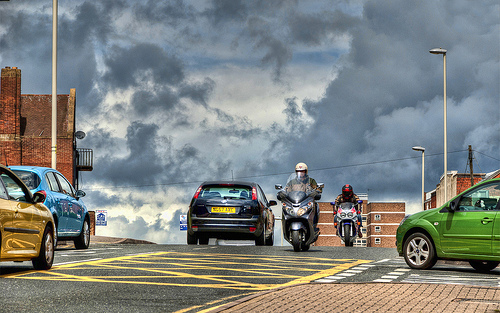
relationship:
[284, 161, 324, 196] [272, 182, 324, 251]
person riding bike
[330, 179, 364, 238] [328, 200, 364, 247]
person riding bike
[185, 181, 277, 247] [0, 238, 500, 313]
car on ground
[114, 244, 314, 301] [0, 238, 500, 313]
line on ground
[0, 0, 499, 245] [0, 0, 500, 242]
clouds in sky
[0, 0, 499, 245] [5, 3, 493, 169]
clouds in sky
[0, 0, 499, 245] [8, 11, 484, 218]
clouds in sky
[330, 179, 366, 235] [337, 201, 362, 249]
person on motorcycle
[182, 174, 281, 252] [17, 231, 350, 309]
car on pavement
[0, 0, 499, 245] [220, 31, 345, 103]
clouds in sky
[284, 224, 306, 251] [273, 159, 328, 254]
front tire of bike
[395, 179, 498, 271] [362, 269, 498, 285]
car on ground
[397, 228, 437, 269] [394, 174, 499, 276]
tire of car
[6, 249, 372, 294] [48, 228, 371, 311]
line on ground